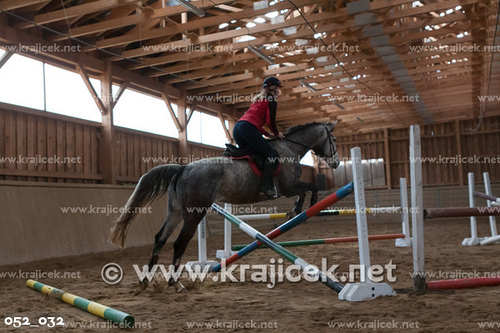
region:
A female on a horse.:
[108, 74, 342, 286]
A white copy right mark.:
[99, 258, 399, 286]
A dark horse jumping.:
[108, 119, 342, 293]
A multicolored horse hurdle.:
[184, 146, 396, 303]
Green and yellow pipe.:
[24, 276, 136, 329]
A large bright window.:
[0, 45, 103, 125]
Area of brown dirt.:
[1, 217, 499, 332]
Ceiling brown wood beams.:
[0, 0, 498, 135]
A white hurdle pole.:
[407, 122, 424, 275]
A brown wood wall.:
[0, 103, 225, 183]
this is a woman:
[216, 74, 291, 167]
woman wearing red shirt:
[236, 92, 279, 132]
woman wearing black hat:
[260, 62, 288, 93]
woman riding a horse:
[91, 70, 364, 279]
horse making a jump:
[96, 47, 381, 322]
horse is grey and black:
[105, 107, 353, 278]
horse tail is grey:
[86, 140, 207, 267]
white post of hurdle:
[323, 145, 411, 325]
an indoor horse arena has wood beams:
[11, 3, 498, 328]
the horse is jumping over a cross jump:
[105, 113, 342, 296]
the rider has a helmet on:
[247, 71, 287, 106]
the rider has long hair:
[247, 73, 287, 115]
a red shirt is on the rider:
[237, 90, 289, 143]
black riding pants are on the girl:
[232, 115, 279, 187]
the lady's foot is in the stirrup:
[253, 179, 280, 206]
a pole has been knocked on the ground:
[18, 224, 149, 331]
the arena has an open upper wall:
[3, 53, 257, 270]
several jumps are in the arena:
[131, 120, 498, 315]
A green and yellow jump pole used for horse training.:
[24, 277, 137, 324]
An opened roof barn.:
[82, 0, 498, 71]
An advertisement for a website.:
[129, 259, 405, 294]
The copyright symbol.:
[97, 256, 127, 288]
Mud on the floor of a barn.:
[168, 301, 498, 327]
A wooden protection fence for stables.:
[4, 96, 248, 193]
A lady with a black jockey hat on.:
[258, 73, 285, 100]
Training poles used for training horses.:
[339, 124, 499, 331]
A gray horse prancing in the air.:
[110, 120, 360, 289]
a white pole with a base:
[331, 143, 395, 301]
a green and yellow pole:
[18, 272, 139, 331]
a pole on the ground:
[20, 269, 135, 327]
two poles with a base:
[452, 167, 499, 249]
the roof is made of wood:
[3, 6, 499, 134]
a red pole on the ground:
[421, 260, 496, 292]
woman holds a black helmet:
[249, 68, 291, 109]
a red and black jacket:
[232, 88, 285, 143]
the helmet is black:
[263, 75, 282, 86]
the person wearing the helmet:
[231, 77, 283, 202]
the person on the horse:
[106, 78, 338, 290]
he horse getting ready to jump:
[108, 118, 339, 294]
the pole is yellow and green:
[25, 277, 135, 327]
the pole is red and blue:
[211, 180, 356, 272]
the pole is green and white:
[211, 203, 343, 290]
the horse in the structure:
[0, 0, 499, 331]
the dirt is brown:
[0, 216, 499, 331]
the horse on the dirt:
[0, 119, 498, 331]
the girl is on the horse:
[239, 75, 284, 202]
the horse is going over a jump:
[113, 120, 400, 296]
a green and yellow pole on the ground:
[24, 275, 136, 329]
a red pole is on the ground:
[424, 277, 497, 291]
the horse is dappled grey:
[109, 118, 340, 287]